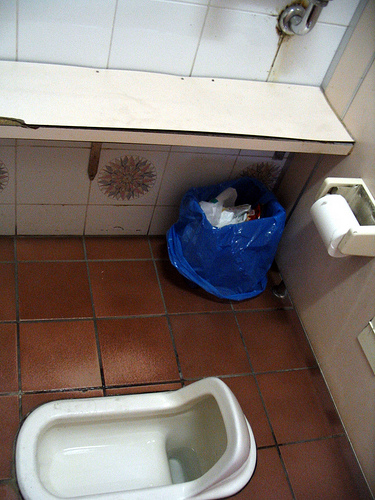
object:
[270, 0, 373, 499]
wall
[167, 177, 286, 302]
garbage can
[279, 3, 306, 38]
rust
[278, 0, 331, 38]
pipe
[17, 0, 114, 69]
tile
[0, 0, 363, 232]
wall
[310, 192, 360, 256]
roll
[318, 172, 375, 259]
holder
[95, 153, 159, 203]
circle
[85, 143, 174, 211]
tile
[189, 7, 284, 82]
white tile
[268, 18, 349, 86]
white tile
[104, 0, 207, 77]
white tile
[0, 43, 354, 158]
counter top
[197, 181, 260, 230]
trash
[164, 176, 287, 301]
bag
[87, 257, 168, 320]
tile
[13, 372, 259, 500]
toilet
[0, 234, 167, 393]
floor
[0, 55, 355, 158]
bench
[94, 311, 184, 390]
tile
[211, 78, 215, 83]
nail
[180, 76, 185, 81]
nail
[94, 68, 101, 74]
nail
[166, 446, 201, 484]
water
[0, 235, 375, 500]
floor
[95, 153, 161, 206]
design